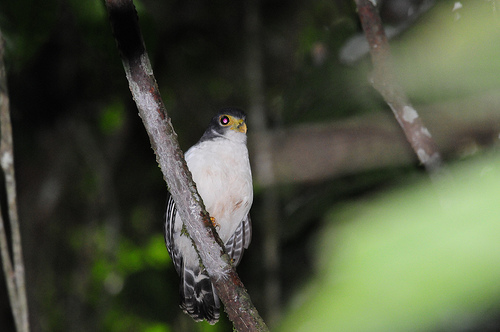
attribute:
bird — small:
[163, 106, 255, 326]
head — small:
[206, 108, 248, 144]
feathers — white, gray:
[172, 138, 250, 277]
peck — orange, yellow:
[236, 121, 246, 135]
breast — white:
[182, 138, 252, 205]